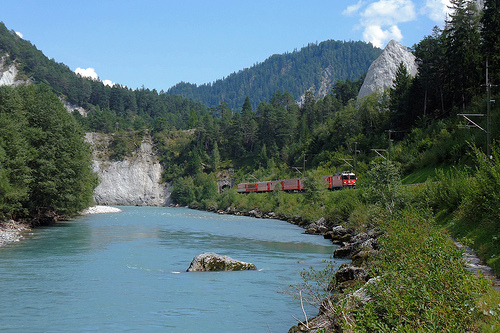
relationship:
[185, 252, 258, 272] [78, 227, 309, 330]
rock in water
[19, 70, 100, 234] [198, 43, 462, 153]
evergreen tree over mountain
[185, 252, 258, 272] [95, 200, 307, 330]
rock in water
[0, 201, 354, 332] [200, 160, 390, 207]
lake by train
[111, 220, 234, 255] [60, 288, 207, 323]
waves in water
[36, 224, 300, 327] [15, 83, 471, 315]
lake in valley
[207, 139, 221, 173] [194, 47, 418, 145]
trees on mountain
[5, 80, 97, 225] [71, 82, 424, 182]
trees on mountain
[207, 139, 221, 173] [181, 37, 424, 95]
trees on mountain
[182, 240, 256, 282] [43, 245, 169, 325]
rock in water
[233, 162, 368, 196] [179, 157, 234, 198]
train came from tunnel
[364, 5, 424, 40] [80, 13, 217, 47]
clouds in sky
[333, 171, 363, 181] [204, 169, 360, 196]
windshield on train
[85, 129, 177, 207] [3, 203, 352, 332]
cliff face behind river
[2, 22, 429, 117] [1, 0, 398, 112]
mountain in background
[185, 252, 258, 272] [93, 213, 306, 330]
rock in water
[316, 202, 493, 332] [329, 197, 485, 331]
bushes in row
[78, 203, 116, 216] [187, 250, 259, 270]
hill ground has rock